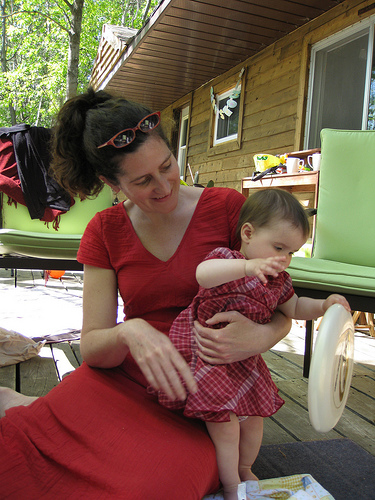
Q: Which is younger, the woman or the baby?
A: The baby is younger than the woman.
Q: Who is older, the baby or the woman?
A: The woman is older than the baby.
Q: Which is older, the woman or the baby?
A: The woman is older than the baby.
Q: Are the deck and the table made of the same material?
A: Yes, both the deck and the table are made of wood.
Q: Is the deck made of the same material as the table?
A: Yes, both the deck and the table are made of wood.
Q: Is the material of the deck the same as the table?
A: Yes, both the deck and the table are made of wood.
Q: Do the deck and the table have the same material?
A: Yes, both the deck and the table are made of wood.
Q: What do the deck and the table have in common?
A: The material, both the deck and the table are wooden.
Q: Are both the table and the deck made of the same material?
A: Yes, both the table and the deck are made of wood.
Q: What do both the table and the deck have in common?
A: The material, both the table and the deck are wooden.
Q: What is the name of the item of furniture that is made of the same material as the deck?
A: The piece of furniture is a table.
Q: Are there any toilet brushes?
A: No, there are no toilet brushes.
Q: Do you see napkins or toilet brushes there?
A: No, there are no toilet brushes or napkins.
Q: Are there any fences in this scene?
A: No, there are no fences.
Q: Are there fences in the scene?
A: No, there are no fences.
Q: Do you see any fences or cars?
A: No, there are no fences or cars.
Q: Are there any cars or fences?
A: No, there are no fences or cars.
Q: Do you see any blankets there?
A: Yes, there is a blanket.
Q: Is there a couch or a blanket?
A: Yes, there is a blanket.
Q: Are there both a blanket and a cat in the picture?
A: No, there is a blanket but no cats.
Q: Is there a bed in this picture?
A: No, there are no beds.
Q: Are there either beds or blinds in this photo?
A: No, there are no beds or blinds.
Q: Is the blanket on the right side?
A: Yes, the blanket is on the right of the image.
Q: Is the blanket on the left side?
A: No, the blanket is on the right of the image.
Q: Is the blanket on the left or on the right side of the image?
A: The blanket is on the right of the image.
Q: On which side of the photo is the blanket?
A: The blanket is on the right of the image.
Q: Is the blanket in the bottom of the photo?
A: Yes, the blanket is in the bottom of the image.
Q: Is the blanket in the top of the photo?
A: No, the blanket is in the bottom of the image.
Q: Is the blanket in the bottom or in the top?
A: The blanket is in the bottom of the image.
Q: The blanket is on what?
A: The blanket is on the deck.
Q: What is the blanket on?
A: The blanket is on the deck.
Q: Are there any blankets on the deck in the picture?
A: Yes, there is a blanket on the deck.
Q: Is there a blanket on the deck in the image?
A: Yes, there is a blanket on the deck.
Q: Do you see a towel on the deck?
A: No, there is a blanket on the deck.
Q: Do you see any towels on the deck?
A: No, there is a blanket on the deck.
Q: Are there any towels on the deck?
A: No, there is a blanket on the deck.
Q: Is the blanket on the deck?
A: Yes, the blanket is on the deck.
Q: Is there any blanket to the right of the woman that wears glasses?
A: Yes, there is a blanket to the right of the woman.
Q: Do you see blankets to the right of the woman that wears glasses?
A: Yes, there is a blanket to the right of the woman.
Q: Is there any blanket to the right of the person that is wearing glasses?
A: Yes, there is a blanket to the right of the woman.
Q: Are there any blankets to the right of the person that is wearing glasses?
A: Yes, there is a blanket to the right of the woman.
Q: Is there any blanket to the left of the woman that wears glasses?
A: No, the blanket is to the right of the woman.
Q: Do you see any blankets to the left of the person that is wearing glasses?
A: No, the blanket is to the right of the woman.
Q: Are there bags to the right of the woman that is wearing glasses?
A: No, there is a blanket to the right of the woman.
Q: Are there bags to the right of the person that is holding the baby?
A: No, there is a blanket to the right of the woman.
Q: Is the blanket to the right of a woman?
A: Yes, the blanket is to the right of a woman.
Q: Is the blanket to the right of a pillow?
A: No, the blanket is to the right of a woman.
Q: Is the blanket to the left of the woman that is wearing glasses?
A: No, the blanket is to the right of the woman.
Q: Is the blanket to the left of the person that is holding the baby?
A: No, the blanket is to the right of the woman.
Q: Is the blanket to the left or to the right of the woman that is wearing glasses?
A: The blanket is to the right of the woman.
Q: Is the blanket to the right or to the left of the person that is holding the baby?
A: The blanket is to the right of the woman.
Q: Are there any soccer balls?
A: No, there are no soccer balls.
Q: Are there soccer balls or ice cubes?
A: No, there are no soccer balls or ice cubes.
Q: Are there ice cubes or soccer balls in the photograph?
A: No, there are no soccer balls or ice cubes.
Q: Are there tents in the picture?
A: No, there are no tents.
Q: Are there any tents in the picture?
A: No, there are no tents.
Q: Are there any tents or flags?
A: No, there are no tents or flags.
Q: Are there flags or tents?
A: No, there are no tents or flags.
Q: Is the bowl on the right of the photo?
A: Yes, the bowl is on the right of the image.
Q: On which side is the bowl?
A: The bowl is on the right of the image.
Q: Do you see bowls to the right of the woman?
A: Yes, there is a bowl to the right of the woman.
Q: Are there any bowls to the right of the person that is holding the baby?
A: Yes, there is a bowl to the right of the woman.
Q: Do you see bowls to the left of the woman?
A: No, the bowl is to the right of the woman.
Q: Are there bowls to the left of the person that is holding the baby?
A: No, the bowl is to the right of the woman.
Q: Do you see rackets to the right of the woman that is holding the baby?
A: No, there is a bowl to the right of the woman.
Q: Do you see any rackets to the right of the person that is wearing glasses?
A: No, there is a bowl to the right of the woman.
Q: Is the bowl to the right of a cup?
A: No, the bowl is to the right of the woman.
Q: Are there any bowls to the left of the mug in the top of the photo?
A: Yes, there is a bowl to the left of the mug.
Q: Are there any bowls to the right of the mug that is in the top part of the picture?
A: No, the bowl is to the left of the mug.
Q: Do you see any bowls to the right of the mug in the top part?
A: No, the bowl is to the left of the mug.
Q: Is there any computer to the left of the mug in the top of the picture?
A: No, there is a bowl to the left of the mug.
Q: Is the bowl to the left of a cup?
A: No, the bowl is to the left of a mug.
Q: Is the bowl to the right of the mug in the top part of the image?
A: No, the bowl is to the left of the mug.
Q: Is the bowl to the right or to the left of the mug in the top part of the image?
A: The bowl is to the left of the mug.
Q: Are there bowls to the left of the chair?
A: Yes, there is a bowl to the left of the chair.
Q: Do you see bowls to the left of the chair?
A: Yes, there is a bowl to the left of the chair.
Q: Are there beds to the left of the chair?
A: No, there is a bowl to the left of the chair.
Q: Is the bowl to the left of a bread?
A: No, the bowl is to the left of a chair.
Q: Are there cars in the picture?
A: No, there are no cars.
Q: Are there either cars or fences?
A: No, there are no cars or fences.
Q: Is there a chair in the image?
A: Yes, there is a chair.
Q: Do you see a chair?
A: Yes, there is a chair.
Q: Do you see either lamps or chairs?
A: Yes, there is a chair.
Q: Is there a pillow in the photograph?
A: No, there are no pillows.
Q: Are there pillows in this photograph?
A: No, there are no pillows.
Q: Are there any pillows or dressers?
A: No, there are no pillows or dressers.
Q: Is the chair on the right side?
A: Yes, the chair is on the right of the image.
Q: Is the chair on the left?
A: No, the chair is on the right of the image.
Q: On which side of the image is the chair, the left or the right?
A: The chair is on the right of the image.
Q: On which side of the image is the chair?
A: The chair is on the right of the image.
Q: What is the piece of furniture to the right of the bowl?
A: The piece of furniture is a chair.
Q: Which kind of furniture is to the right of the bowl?
A: The piece of furniture is a chair.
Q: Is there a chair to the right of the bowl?
A: Yes, there is a chair to the right of the bowl.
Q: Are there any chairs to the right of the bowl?
A: Yes, there is a chair to the right of the bowl.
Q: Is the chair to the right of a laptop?
A: No, the chair is to the right of a bowl.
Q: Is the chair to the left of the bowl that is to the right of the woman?
A: No, the chair is to the right of the bowl.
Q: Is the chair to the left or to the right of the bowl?
A: The chair is to the right of the bowl.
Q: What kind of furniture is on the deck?
A: The piece of furniture is a chair.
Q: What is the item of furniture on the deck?
A: The piece of furniture is a chair.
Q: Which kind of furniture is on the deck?
A: The piece of furniture is a chair.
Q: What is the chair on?
A: The chair is on the deck.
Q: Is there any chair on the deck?
A: Yes, there is a chair on the deck.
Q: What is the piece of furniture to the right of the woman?
A: The piece of furniture is a chair.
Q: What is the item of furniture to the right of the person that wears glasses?
A: The piece of furniture is a chair.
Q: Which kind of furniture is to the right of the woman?
A: The piece of furniture is a chair.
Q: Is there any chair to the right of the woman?
A: Yes, there is a chair to the right of the woman.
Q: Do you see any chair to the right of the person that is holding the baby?
A: Yes, there is a chair to the right of the woman.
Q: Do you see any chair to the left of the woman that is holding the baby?
A: No, the chair is to the right of the woman.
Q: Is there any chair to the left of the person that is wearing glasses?
A: No, the chair is to the right of the woman.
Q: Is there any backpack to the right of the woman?
A: No, there is a chair to the right of the woman.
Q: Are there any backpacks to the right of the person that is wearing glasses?
A: No, there is a chair to the right of the woman.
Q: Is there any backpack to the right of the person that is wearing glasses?
A: No, there is a chair to the right of the woman.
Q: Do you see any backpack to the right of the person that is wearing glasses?
A: No, there is a chair to the right of the woman.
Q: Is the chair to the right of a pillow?
A: No, the chair is to the right of a woman.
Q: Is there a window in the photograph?
A: Yes, there is a window.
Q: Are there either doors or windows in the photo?
A: Yes, there is a window.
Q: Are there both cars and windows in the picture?
A: No, there is a window but no cars.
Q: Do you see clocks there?
A: No, there are no clocks.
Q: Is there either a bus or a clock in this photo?
A: No, there are no clocks or buses.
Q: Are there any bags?
A: No, there are no bags.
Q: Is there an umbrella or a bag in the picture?
A: No, there are no bags or umbrellas.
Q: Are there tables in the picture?
A: Yes, there is a table.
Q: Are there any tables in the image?
A: Yes, there is a table.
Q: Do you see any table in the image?
A: Yes, there is a table.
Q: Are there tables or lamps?
A: Yes, there is a table.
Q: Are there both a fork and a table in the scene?
A: No, there is a table but no forks.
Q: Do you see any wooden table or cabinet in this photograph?
A: Yes, there is a wood table.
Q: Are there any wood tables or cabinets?
A: Yes, there is a wood table.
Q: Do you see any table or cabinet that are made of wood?
A: Yes, the table is made of wood.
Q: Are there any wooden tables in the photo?
A: Yes, there is a wood table.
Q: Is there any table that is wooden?
A: Yes, there is a table that is wooden.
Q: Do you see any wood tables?
A: Yes, there is a table that is made of wood.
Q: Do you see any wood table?
A: Yes, there is a table that is made of wood.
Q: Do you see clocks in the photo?
A: No, there are no clocks.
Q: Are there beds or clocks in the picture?
A: No, there are no clocks or beds.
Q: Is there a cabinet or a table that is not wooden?
A: No, there is a table but it is wooden.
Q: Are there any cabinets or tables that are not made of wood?
A: No, there is a table but it is made of wood.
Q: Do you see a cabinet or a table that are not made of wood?
A: No, there is a table but it is made of wood.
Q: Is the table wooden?
A: Yes, the table is wooden.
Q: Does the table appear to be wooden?
A: Yes, the table is wooden.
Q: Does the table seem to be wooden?
A: Yes, the table is wooden.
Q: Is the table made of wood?
A: Yes, the table is made of wood.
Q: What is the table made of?
A: The table is made of wood.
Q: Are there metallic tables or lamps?
A: No, there is a table but it is wooden.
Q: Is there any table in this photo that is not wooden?
A: No, there is a table but it is wooden.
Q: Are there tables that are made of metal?
A: No, there is a table but it is made of wood.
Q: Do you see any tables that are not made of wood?
A: No, there is a table but it is made of wood.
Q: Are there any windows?
A: Yes, there is a window.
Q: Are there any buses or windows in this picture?
A: Yes, there is a window.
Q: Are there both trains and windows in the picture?
A: No, there is a window but no trains.